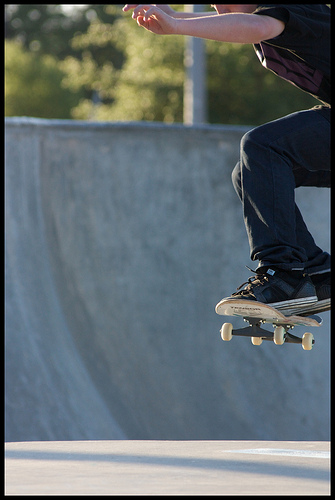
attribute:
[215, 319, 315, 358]
wheels — white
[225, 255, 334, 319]
shoes — black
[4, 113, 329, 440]
ramp — concrete, cement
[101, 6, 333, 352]
skater — crouched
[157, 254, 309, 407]
skateboard — white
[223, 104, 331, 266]
jeans — blue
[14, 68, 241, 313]
fence — blue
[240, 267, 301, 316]
skate shoe — leather, black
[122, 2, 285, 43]
arms — out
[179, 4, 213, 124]
metal pole — gray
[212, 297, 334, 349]
skateboard — black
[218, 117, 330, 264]
pants — dark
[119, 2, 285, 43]
arm — out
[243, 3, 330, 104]
top — black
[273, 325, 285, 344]
wheel — white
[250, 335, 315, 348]
wheels — black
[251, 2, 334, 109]
tee shirt — black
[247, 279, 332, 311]
shoes — black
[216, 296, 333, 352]
skateboard — wood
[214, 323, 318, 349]
wheels — white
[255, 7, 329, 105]
tee shirt — black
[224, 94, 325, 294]
jeans — blue